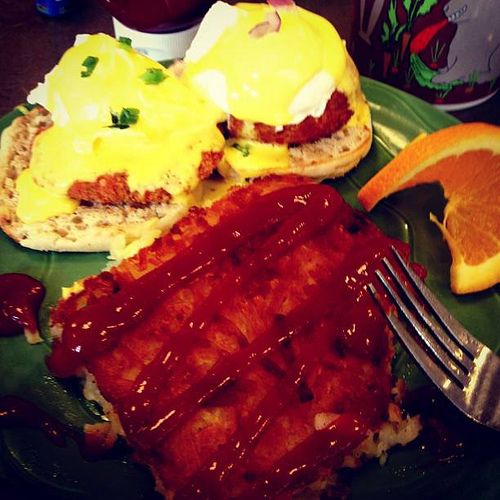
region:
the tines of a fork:
[363, 240, 498, 435]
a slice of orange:
[351, 115, 499, 300]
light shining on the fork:
[459, 341, 495, 411]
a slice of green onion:
[77, 50, 108, 81]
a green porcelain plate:
[1, 72, 498, 498]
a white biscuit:
[2, 105, 204, 257]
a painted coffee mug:
[344, 2, 499, 119]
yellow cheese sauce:
[13, 30, 229, 229]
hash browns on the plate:
[51, 174, 430, 499]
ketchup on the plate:
[5, 262, 52, 345]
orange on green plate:
[356, 126, 497, 293]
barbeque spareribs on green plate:
[13, 182, 423, 499]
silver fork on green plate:
[342, 234, 499, 442]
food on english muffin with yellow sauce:
[9, 36, 224, 245]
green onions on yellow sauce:
[70, 36, 190, 139]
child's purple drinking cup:
[365, 0, 499, 120]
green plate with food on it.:
[10, 70, 499, 499]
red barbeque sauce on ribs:
[57, 187, 334, 372]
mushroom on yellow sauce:
[240, 9, 300, 45]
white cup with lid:
[108, 5, 200, 62]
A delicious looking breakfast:
[53, 44, 498, 478]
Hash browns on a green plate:
[107, 227, 384, 451]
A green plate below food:
[17, 73, 489, 498]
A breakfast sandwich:
[56, 42, 364, 188]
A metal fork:
[377, 239, 498, 409]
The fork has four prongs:
[373, 247, 486, 396]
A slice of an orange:
[350, 103, 498, 276]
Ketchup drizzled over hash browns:
[114, 248, 382, 467]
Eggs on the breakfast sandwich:
[79, 6, 353, 113]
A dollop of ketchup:
[0, 270, 50, 339]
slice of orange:
[377, 123, 497, 290]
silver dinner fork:
[360, 238, 498, 460]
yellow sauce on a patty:
[28, 27, 216, 204]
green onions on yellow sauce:
[67, 41, 172, 133]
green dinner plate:
[363, 67, 450, 151]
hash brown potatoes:
[67, 172, 412, 480]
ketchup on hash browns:
[119, 213, 378, 395]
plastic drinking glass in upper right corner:
[376, 3, 498, 107]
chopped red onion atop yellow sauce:
[237, 4, 291, 43]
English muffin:
[7, 125, 132, 252]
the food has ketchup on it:
[58, 186, 438, 485]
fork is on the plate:
[356, 244, 494, 392]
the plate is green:
[0, 40, 491, 492]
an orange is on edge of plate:
[342, 94, 498, 279]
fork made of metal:
[373, 230, 488, 405]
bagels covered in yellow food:
[13, 23, 445, 202]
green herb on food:
[56, 32, 180, 157]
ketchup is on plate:
[5, 256, 55, 363]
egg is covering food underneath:
[33, 36, 235, 211]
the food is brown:
[72, 169, 164, 216]